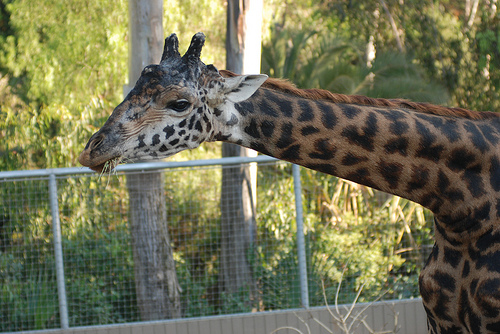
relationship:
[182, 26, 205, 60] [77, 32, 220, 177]
horn on head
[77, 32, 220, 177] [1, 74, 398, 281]
head of giraffe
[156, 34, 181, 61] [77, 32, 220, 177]
horn on head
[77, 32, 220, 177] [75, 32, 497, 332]
head of giraffe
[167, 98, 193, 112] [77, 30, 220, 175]
eye on head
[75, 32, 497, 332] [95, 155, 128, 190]
giraffe eating grass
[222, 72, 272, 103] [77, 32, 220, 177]
ear on head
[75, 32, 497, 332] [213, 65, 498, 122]
giraffe has mane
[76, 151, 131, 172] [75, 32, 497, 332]
mouth of giraffe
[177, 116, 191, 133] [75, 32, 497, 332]
spot on giraffe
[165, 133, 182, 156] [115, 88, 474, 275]
brown spot on giraffe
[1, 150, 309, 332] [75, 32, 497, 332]
fence behind giraffe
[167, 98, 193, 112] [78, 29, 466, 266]
eye of giraffe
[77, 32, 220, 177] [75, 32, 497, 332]
head belonging to giraffe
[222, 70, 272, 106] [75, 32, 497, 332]
ear belonging to giraffe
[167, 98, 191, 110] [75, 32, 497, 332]
eye belonging to giraffe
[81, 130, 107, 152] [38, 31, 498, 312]
nose belonging to giraffe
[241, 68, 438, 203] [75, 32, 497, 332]
neck belonging to giraffe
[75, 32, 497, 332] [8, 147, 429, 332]
giraffe standing near fence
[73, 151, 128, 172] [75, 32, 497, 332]
mouth belonging to giraffe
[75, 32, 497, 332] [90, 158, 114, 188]
giraffe eating straw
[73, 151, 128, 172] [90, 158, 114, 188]
mouth eating straw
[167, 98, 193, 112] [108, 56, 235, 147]
eye belonging to giraffe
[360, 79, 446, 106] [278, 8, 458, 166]
palm frond growing on tree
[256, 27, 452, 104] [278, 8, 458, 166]
palm frond growing on tree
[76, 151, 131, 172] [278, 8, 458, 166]
mouth growing on tree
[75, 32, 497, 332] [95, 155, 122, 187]
giraffe eating hay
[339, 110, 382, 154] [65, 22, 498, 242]
spot belonging to giraffe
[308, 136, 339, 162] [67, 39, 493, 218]
spot belonging to giraffe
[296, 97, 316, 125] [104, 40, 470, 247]
spot belonging to giraffe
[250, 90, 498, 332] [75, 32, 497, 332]
brown spot belonging to giraffe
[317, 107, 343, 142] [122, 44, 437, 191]
spot on giraffe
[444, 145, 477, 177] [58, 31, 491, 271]
brown spot on giraffe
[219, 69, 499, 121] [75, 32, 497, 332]
main on giraffe